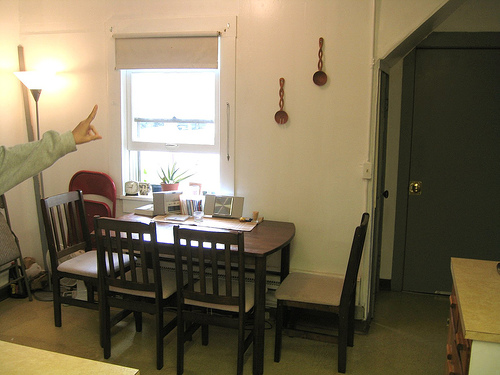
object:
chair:
[40, 189, 137, 327]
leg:
[236, 317, 245, 373]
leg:
[100, 292, 112, 360]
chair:
[66, 169, 117, 251]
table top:
[90, 212, 296, 254]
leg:
[274, 304, 284, 365]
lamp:
[11, 68, 54, 289]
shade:
[111, 30, 219, 70]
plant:
[155, 161, 196, 185]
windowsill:
[122, 189, 218, 200]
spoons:
[273, 36, 328, 124]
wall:
[0, 0, 499, 278]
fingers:
[84, 104, 103, 142]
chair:
[172, 225, 267, 375]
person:
[0, 104, 103, 196]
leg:
[337, 317, 350, 372]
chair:
[273, 212, 369, 373]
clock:
[124, 180, 139, 194]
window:
[120, 35, 220, 196]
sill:
[124, 180, 151, 196]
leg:
[50, 275, 62, 328]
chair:
[92, 215, 194, 370]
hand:
[71, 104, 102, 145]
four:
[41, 189, 370, 375]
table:
[90, 212, 296, 363]